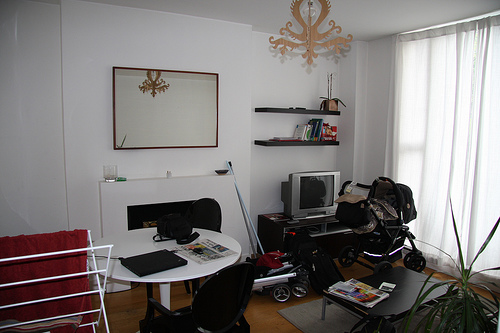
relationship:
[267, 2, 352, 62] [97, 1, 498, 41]
light fixture hangs from ceiling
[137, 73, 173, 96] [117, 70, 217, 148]
reflection in mirror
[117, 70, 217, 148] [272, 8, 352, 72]
mirror of light fixture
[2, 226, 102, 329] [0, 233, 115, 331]
blanket on blanket rack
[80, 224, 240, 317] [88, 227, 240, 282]
table with top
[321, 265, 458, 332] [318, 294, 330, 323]
table with legs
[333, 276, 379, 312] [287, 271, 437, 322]
magazine on corner of table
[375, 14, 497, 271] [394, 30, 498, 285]
drape on window